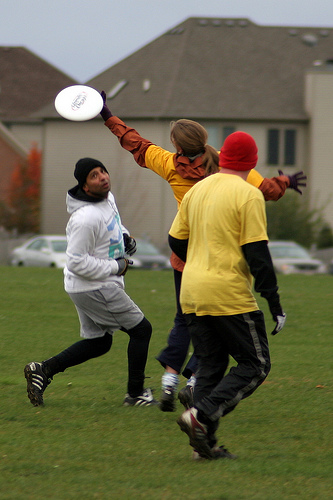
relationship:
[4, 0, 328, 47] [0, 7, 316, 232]
sky behind house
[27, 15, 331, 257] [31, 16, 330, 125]
house has roof